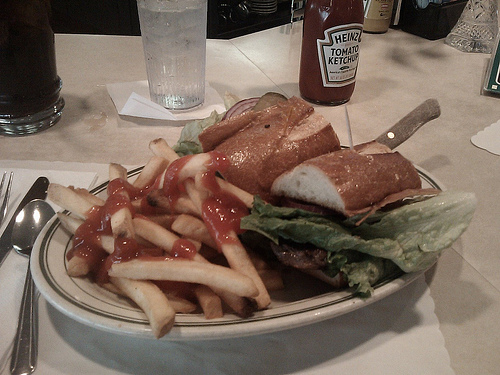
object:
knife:
[0, 176, 55, 259]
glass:
[136, 0, 208, 112]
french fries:
[108, 278, 176, 339]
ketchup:
[197, 191, 249, 242]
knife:
[374, 98, 441, 149]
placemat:
[0, 158, 451, 375]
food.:
[198, 96, 340, 202]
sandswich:
[241, 142, 478, 297]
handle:
[375, 99, 440, 149]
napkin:
[107, 73, 227, 120]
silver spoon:
[11, 199, 58, 375]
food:
[270, 140, 440, 225]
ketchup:
[298, 0, 364, 107]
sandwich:
[174, 92, 341, 200]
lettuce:
[240, 192, 480, 273]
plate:
[30, 154, 448, 343]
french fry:
[198, 170, 271, 309]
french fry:
[66, 246, 98, 277]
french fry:
[108, 256, 259, 297]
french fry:
[46, 184, 96, 219]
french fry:
[106, 162, 134, 235]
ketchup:
[169, 238, 196, 258]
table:
[0, 16, 500, 372]